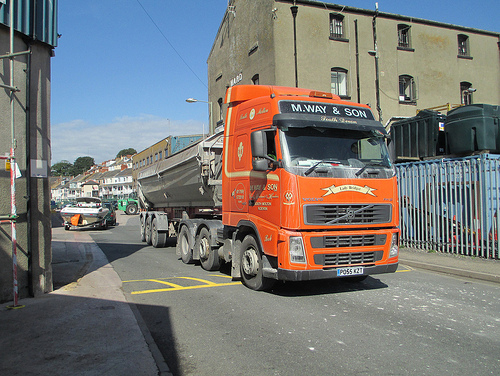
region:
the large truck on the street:
[135, 85, 400, 290]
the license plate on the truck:
[336, 266, 363, 275]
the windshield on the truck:
[282, 125, 391, 167]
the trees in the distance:
[49, 147, 136, 174]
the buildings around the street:
[0, 0, 497, 304]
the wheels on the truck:
[137, 214, 269, 289]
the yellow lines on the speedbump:
[120, 255, 410, 294]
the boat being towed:
[60, 195, 110, 230]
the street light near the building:
[186, 98, 213, 136]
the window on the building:
[328, 13, 345, 39]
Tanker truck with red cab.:
[130, 83, 404, 291]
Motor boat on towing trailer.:
[58, 194, 105, 231]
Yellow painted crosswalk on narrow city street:
[112, 257, 415, 294]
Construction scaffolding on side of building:
[2, 0, 29, 315]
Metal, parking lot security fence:
[397, 153, 499, 261]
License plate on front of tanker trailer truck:
[335, 263, 367, 278]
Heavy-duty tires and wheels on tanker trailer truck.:
[175, 226, 267, 293]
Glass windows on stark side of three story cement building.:
[323, 8, 478, 109]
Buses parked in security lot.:
[390, 101, 499, 161]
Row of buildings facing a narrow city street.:
[51, 129, 208, 225]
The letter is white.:
[288, 99, 303, 111]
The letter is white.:
[301, 98, 316, 115]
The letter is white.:
[313, 100, 323, 117]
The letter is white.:
[320, 101, 329, 116]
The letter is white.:
[342, 105, 353, 117]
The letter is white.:
[350, 105, 359, 119]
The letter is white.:
[356, 108, 368, 121]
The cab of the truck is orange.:
[128, 75, 418, 295]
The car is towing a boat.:
[57, 187, 121, 236]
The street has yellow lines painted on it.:
[101, 204, 446, 321]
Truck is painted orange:
[218, 82, 405, 289]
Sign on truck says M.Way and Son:
[289, 100, 370, 120]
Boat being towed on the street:
[56, 192, 114, 235]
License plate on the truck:
[333, 264, 368, 280]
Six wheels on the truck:
[134, 207, 269, 290]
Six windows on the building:
[324, 10, 477, 109]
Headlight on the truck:
[285, 234, 310, 264]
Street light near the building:
[183, 94, 215, 136]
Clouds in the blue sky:
[49, 114, 208, 176]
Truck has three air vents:
[316, 201, 380, 268]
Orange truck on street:
[149, 91, 443, 315]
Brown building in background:
[190, 4, 498, 132]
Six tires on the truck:
[134, 203, 281, 298]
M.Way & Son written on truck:
[273, 83, 385, 136]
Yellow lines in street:
[116, 262, 263, 304]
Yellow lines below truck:
[122, 233, 249, 309]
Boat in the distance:
[60, 183, 125, 247]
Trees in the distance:
[54, 144, 115, 183]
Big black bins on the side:
[398, 102, 499, 164]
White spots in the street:
[301, 283, 498, 350]